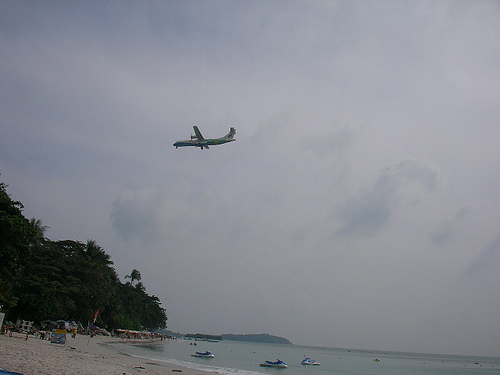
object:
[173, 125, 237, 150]
plane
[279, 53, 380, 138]
sky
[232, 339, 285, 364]
water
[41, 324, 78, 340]
people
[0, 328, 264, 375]
beach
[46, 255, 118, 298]
trees